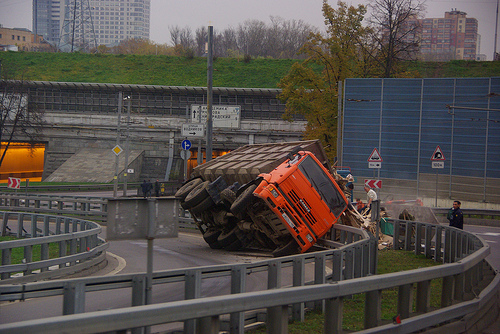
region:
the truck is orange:
[148, 123, 424, 288]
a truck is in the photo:
[151, 114, 383, 270]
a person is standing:
[433, 196, 475, 271]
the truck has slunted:
[146, 126, 403, 286]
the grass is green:
[27, 51, 228, 85]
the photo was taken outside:
[2, 2, 493, 331]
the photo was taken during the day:
[4, 5, 499, 332]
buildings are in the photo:
[25, 3, 202, 69]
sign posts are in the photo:
[426, 142, 452, 189]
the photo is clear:
[4, 2, 485, 332]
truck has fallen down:
[212, 148, 343, 241]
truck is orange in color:
[261, 169, 322, 216]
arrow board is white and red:
[1, 173, 26, 196]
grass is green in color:
[381, 246, 421, 266]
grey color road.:
[130, 246, 158, 263]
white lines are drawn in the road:
[106, 250, 128, 279]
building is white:
[103, 3, 147, 40]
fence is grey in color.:
[253, 256, 310, 286]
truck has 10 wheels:
[171, 174, 313, 270]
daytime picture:
[30, 101, 436, 313]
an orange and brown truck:
[177, 142, 353, 248]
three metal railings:
[30, 227, 492, 302]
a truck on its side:
[173, 141, 354, 246]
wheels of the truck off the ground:
[173, 174, 268, 225]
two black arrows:
[176, 104, 210, 139]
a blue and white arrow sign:
[181, 137, 193, 152]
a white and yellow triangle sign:
[109, 144, 124, 156]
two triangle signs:
[359, 140, 451, 167]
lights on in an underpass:
[163, 132, 225, 174]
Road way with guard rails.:
[93, 238, 257, 287]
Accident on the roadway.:
[156, 127, 431, 279]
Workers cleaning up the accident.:
[307, 150, 462, 277]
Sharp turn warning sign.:
[8, 150, 178, 246]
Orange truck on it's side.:
[224, 124, 379, 299]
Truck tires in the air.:
[161, 166, 257, 214]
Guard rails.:
[198, 240, 359, 320]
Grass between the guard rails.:
[258, 207, 498, 307]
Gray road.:
[133, 220, 212, 286]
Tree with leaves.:
[283, 48, 435, 95]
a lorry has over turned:
[181, 143, 375, 281]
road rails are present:
[38, 252, 120, 330]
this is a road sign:
[433, 147, 447, 177]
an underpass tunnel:
[1, 150, 47, 185]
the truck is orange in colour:
[277, 154, 338, 237]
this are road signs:
[184, 108, 231, 152]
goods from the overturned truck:
[343, 186, 448, 331]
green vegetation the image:
[26, 37, 283, 102]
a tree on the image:
[306, 47, 338, 167]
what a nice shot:
[12, 38, 446, 327]